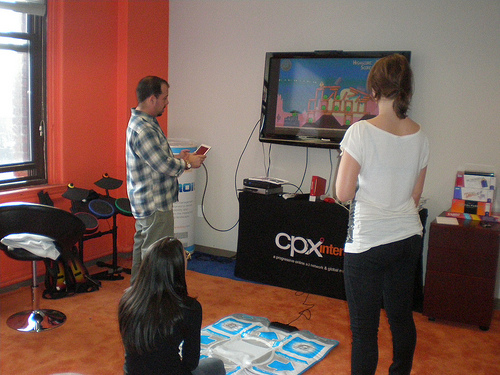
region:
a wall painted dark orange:
[60, 17, 123, 113]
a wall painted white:
[187, 32, 242, 117]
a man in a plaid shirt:
[112, 67, 195, 237]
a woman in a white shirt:
[327, 37, 468, 354]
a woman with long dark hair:
[105, 227, 234, 373]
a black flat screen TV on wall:
[251, 36, 411, 152]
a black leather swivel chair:
[2, 193, 84, 342]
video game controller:
[186, 128, 229, 192]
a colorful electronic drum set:
[64, 161, 137, 293]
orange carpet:
[67, 316, 116, 363]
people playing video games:
[121, 74, 405, 374]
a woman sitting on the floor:
[114, 247, 217, 374]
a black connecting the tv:
[202, 165, 228, 236]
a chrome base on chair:
[6, 263, 61, 334]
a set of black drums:
[71, 180, 131, 224]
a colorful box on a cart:
[449, 171, 493, 218]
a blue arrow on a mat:
[270, 356, 297, 373]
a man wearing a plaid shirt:
[126, 72, 201, 226]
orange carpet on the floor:
[54, 327, 108, 370]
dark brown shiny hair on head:
[150, 255, 180, 310]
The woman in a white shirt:
[322, 36, 432, 373]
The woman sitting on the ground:
[110, 220, 235, 373]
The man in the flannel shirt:
[117, 70, 208, 287]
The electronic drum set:
[67, 176, 142, 281]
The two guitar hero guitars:
[36, 186, 102, 297]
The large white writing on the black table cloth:
[270, 227, 323, 263]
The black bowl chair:
[0, 197, 87, 263]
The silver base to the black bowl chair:
[6, 257, 66, 333]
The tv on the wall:
[251, 42, 413, 154]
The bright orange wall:
[0, 0, 173, 290]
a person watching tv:
[332, 2, 418, 369]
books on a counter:
[427, 167, 493, 235]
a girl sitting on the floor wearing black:
[121, 239, 198, 370]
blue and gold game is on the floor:
[203, 306, 338, 371]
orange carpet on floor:
[25, 287, 488, 369]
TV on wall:
[257, 33, 431, 150]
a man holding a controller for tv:
[106, 68, 217, 240]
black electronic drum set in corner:
[68, 167, 132, 287]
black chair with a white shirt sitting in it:
[4, 190, 80, 345]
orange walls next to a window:
[0, 47, 177, 192]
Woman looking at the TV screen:
[335, 50, 430, 371]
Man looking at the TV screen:
[120, 71, 210, 276]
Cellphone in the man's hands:
[191, 140, 207, 155]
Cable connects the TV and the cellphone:
[200, 120, 260, 230]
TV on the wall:
[257, 51, 412, 143]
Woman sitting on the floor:
[116, 236, 226, 373]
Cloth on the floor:
[180, 310, 338, 372]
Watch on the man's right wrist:
[184, 158, 193, 168]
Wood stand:
[424, 213, 499, 333]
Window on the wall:
[1, 8, 48, 186]